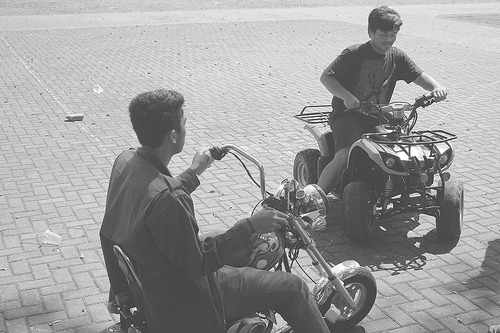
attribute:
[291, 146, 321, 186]
tire — small, rubber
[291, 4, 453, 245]
man — young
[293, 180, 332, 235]
headlight — shiny, metal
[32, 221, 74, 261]
cup — plastic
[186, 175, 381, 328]
bike — low rider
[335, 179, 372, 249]
rubber tire — small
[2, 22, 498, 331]
surface — brick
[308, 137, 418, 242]
vehicle — low rider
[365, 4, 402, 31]
hair — bushy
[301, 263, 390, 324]
tire — small, rubber